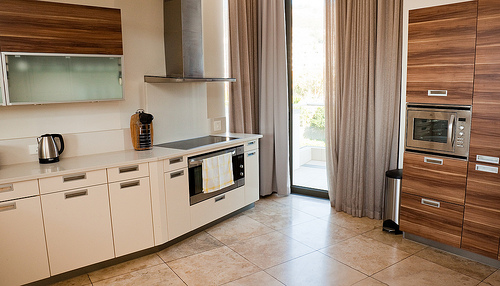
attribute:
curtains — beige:
[229, 2, 394, 225]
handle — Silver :
[418, 199, 442, 210]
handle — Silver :
[479, 158, 498, 180]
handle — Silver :
[478, 154, 494, 169]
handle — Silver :
[118, 170, 150, 196]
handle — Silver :
[67, 188, 108, 208]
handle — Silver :
[0, 203, 22, 207]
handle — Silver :
[64, 169, 90, 185]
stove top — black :
[145, 125, 241, 155]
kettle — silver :
[34, 130, 68, 169]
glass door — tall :
[287, 2, 333, 200]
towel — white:
[199, 153, 245, 198]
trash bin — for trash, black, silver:
[378, 162, 400, 237]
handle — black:
[46, 127, 73, 157]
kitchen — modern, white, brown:
[31, 48, 443, 240]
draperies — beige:
[226, 14, 393, 214]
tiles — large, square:
[177, 239, 307, 279]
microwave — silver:
[397, 98, 480, 157]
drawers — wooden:
[401, 38, 458, 236]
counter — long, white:
[17, 145, 259, 225]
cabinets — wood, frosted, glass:
[7, 34, 115, 103]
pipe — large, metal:
[151, 4, 221, 80]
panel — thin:
[127, 58, 246, 107]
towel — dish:
[195, 145, 264, 205]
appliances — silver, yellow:
[21, 124, 179, 164]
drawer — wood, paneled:
[408, 39, 477, 102]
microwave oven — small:
[396, 102, 473, 158]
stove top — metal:
[157, 120, 269, 190]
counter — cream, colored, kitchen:
[9, 139, 249, 237]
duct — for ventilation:
[147, 10, 232, 101]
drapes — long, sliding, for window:
[231, 10, 389, 229]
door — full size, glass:
[289, 8, 328, 197]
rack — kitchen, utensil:
[126, 112, 180, 160]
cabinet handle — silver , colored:
[417, 149, 449, 174]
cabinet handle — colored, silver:
[427, 85, 453, 102]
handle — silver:
[467, 153, 498, 166]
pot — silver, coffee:
[34, 130, 65, 164]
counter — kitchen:
[1, 113, 265, 183]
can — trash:
[379, 166, 405, 234]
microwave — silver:
[402, 101, 473, 160]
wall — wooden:
[395, 0, 484, 257]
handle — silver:
[116, 164, 139, 174]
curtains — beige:
[226, 0, 404, 219]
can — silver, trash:
[377, 166, 404, 235]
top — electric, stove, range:
[152, 130, 243, 149]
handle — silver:
[63, 188, 90, 200]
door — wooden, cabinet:
[404, 1, 480, 107]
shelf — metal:
[142, 74, 233, 84]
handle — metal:
[426, 87, 449, 97]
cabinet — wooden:
[404, 1, 479, 106]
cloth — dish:
[200, 150, 237, 194]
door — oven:
[184, 142, 245, 205]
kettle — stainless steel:
[35, 130, 65, 164]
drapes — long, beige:
[328, 0, 400, 225]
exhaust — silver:
[130, 2, 259, 108]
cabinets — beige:
[2, 155, 183, 278]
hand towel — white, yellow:
[199, 150, 246, 200]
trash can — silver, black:
[372, 160, 414, 239]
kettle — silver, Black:
[31, 126, 70, 177]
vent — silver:
[138, 0, 242, 121]